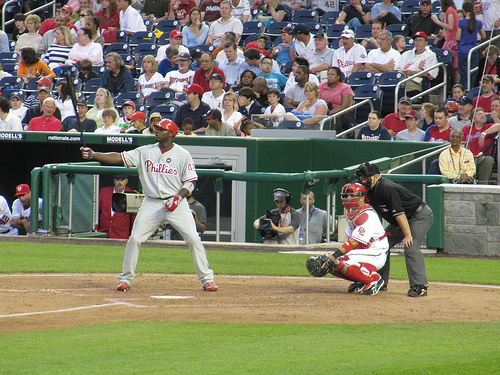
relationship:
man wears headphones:
[253, 177, 300, 237] [266, 181, 293, 211]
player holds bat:
[75, 104, 222, 300] [53, 62, 91, 149]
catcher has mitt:
[319, 171, 400, 301] [297, 245, 337, 283]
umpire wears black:
[355, 152, 442, 302] [372, 170, 441, 282]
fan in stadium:
[313, 57, 356, 109] [1, 1, 491, 362]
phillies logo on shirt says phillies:
[137, 155, 180, 180] [123, 145, 200, 207]